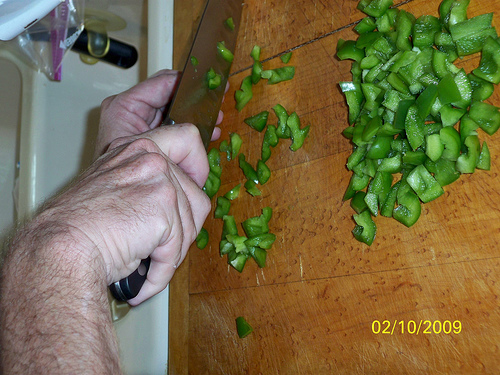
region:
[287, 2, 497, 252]
green peppers on wooden table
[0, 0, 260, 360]
white male holding big knife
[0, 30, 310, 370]
white male cutting green peppers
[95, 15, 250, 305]
big knife with black handle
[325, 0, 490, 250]
finely cut pile of green peppers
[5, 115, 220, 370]
white male with hairy forearms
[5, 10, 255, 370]
white male cutting peppers on wooden table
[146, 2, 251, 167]
green peppers on knife head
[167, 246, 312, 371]
white scratches on brown table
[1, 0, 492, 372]
white male cutting green peppers on even numbered day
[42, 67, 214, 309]
The right hand of a man.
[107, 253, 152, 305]
Black and silver end of a knife.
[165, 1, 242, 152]
Silver blade of a knife.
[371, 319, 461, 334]
The date 02/10/2009.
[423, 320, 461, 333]
The year 2009.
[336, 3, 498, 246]
A large pile of chopped green pepper.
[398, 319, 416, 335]
Yellow number 10.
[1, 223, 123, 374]
Hairy arm of a man.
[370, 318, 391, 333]
A yellow 02.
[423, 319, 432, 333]
Yellow 2 in 2009.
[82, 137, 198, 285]
this is a hand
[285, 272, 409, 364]
this is a chopping board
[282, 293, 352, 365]
the board is brown in colour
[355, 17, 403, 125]
these are green paper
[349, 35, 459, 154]
the pepper are green in colour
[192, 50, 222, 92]
this is a knife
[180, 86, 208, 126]
the knife is mettalic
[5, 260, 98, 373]
this is the arm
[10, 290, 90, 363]
the arms are hairy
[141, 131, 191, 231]
these are fingrs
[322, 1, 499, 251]
chopped green peppers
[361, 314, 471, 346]
date in yellow print on photo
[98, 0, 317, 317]
knife cutting green peppers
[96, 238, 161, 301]
black handle of knife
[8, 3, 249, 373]
hand holding knife handle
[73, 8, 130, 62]
suction cup on wall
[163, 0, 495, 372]
wooden cutting board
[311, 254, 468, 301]
striation marks on wooden cutting board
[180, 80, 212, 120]
reflection of green pepper in blade of knife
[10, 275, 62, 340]
hair on arm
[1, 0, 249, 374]
Man chopping green peppers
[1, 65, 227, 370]
Hairy man's arm holding a knife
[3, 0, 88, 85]
Plastic bag with pink zipper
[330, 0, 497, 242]
Chopped and diced green peppers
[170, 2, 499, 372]
Light brown wood cutting board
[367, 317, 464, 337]
Yellow date numbers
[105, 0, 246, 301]
Large metal knife with black handle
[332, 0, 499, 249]
Green peppers on a cutting board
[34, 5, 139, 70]
Black object in a plastic holder